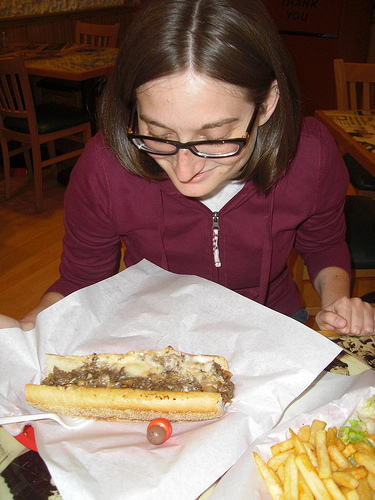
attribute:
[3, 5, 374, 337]
woman — smiling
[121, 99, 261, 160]
glasses — black, brown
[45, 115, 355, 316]
sweater — maroon, plum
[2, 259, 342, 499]
paper — white, crinkled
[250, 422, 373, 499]
fries — golden, golden yellow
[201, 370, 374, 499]
paper — white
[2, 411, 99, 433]
fork — plastic, white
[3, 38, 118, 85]
table — square, brown, wood, empty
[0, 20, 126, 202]
chairs — brown, wood, empty, wooden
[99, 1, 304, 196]
hair — brown, curled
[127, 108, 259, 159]
frames — dark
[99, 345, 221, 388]
cheese — melt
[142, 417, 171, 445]
object — small, brown, orange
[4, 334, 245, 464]
plate — red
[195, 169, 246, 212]
t-shirt — white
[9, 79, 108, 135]
seat — black